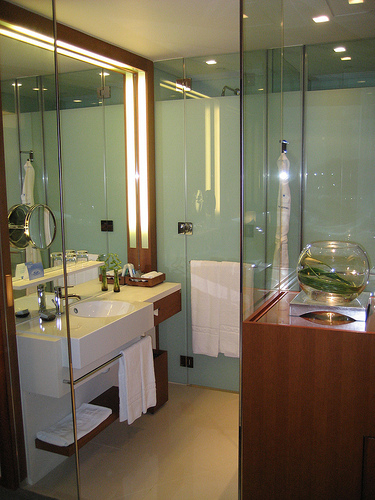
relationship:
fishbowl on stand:
[297, 243, 371, 303] [238, 291, 374, 497]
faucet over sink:
[51, 285, 79, 313] [69, 300, 133, 320]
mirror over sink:
[1, 35, 124, 277] [69, 300, 133, 320]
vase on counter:
[112, 271, 122, 292] [16, 282, 181, 397]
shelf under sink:
[35, 384, 120, 458] [69, 300, 133, 320]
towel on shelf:
[35, 400, 115, 446] [35, 384, 120, 458]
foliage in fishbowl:
[299, 274, 363, 297] [297, 243, 371, 303]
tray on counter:
[124, 274, 166, 285] [16, 282, 181, 397]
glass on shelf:
[67, 252, 78, 269] [13, 261, 104, 289]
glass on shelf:
[77, 252, 88, 264] [13, 261, 104, 289]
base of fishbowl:
[285, 287, 372, 321] [297, 243, 371, 303]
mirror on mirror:
[26, 205, 56, 250] [1, 35, 124, 277]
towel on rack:
[119, 335, 159, 422] [65, 355, 122, 388]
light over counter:
[123, 66, 151, 248] [16, 282, 181, 397]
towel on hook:
[269, 152, 291, 292] [276, 139, 289, 159]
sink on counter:
[69, 300, 133, 320] [16, 282, 181, 397]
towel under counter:
[119, 335, 159, 422] [16, 282, 181, 397]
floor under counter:
[33, 386, 242, 497] [16, 282, 181, 397]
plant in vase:
[109, 254, 122, 271] [112, 271, 122, 292]